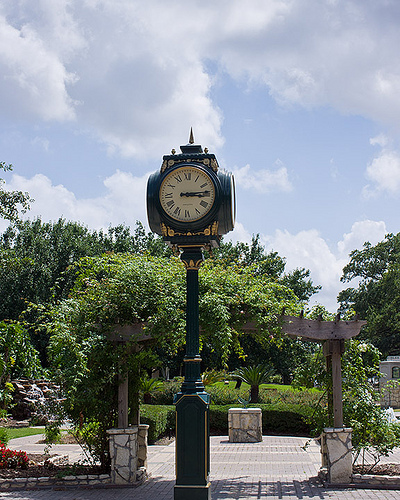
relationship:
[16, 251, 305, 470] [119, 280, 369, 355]
plants on top of arch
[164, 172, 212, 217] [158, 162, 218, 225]
numerals on a clock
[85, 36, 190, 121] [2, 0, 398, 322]
cloud in sky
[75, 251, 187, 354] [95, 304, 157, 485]
plants falling over wooden structure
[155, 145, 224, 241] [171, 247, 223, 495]
clock on pole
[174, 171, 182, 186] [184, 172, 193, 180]
number 11 on romannumeral 12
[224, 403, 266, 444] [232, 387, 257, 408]
square block top of green sculpture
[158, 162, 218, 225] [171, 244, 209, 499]
clock with pole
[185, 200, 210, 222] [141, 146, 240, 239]
number 5 in roman numerals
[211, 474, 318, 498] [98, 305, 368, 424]
shadow of arch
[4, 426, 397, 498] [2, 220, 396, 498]
walkway in garden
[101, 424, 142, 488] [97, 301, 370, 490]
stone post on arbor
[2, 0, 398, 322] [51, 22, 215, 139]
sky with clouds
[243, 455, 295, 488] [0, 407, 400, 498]
floor on floor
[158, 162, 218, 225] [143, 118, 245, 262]
clock on cube